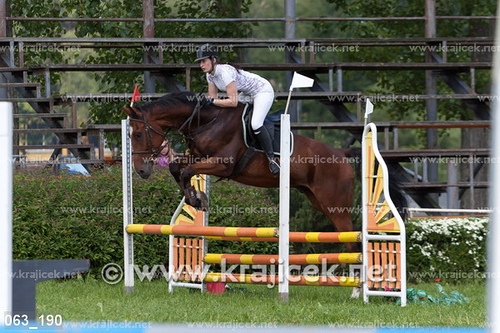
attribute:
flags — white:
[281, 69, 378, 116]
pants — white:
[248, 73, 275, 130]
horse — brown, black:
[115, 82, 342, 303]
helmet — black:
[194, 42, 220, 61]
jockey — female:
[192, 41, 286, 138]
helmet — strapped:
[186, 36, 223, 65]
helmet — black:
[194, 44, 216, 59]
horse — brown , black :
[93, 108, 416, 253]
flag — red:
[128, 85, 140, 103]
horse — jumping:
[126, 86, 361, 233]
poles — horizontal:
[115, 113, 411, 308]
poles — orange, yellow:
[126, 223, 362, 285]